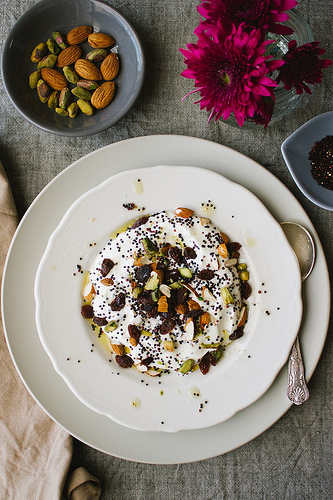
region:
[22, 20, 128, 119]
the nuts in the grey bowl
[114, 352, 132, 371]
a raisin on the plate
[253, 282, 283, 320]
black dots on the white plate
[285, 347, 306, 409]
the design on the end of the spoon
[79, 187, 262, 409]
the yougurt on the bowl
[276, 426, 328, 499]
the creases in the table cloth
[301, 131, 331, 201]
the pepper in the blue bowl by the plate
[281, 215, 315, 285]
the round end of the spoon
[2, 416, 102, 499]
the napkin under the white plate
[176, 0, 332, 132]
the pink flowers in the mason jar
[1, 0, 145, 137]
Almonds and pistachios in a gray bowl.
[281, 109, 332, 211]
Spices in a gray bowl.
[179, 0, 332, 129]
Pink flowers in a glass vase.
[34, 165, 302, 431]
Bowl of yogurt with nuts in it.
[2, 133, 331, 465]
White bowl of food on a white plate.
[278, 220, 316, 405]
Silver spoon on a white plate.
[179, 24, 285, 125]
Biggest pink flower with a green center.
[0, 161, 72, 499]
Beige napkin on a table.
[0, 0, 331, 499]
The tablecloth is gray.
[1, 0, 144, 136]
Round gray bowl full of nuts.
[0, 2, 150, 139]
Almonds and pistachios in gray bowl.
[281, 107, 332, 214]
A dish of poppy seeds.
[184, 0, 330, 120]
Purple flowers in clear glass jar.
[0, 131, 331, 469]
Two white round plates.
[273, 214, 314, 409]
Spoon laying on a plate.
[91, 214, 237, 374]
Raisins, nuts, and seeds on cream cheese.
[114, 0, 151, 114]
Light reflecting on gray bowl.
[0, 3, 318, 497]
Gray table cloth under dishes.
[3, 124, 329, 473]
Small plate on top of larger plate.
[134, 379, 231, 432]
Poppy seeds on side of plate.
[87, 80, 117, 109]
A brown wal nut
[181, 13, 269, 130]
A purple flower in vase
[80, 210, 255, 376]
A desert soup in a bowl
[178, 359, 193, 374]
A green fruit piece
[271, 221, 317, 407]
A small silver spoon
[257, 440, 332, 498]
A granite counter top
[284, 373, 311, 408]
Bottom of silver spoon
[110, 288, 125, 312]
brown fried raisan fruit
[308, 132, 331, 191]
A bowl of spices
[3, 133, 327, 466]
silver spoon between two white plates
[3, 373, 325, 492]
white, tan and gray table linens under plates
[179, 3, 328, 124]
dark red flowers in water in glass container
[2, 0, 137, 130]
almonds and pistachios in small gray bowl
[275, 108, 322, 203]
pointed bowl with dark seeds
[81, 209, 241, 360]
white yogurt topped with nuts, raisins and seeds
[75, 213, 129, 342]
sweet yellow syrup on side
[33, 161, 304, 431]
curved rim of smaller white plate